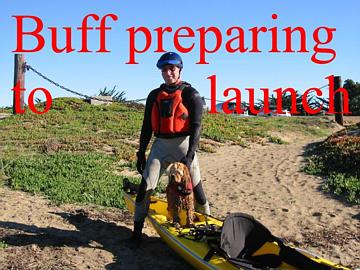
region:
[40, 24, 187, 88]
the sky is visible and clear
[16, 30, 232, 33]
the sky is visible and clear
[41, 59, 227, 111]
the sky is visible and clear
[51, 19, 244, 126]
the sky is visible and clear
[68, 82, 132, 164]
a rope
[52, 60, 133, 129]
a rope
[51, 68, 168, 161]
a rope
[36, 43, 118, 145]
a rope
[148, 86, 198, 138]
black and orange life vest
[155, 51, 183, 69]
a helmet for safety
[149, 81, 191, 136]
an orange life vest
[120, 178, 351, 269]
a yellow ocean kayak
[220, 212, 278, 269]
a black vinyl kayak seat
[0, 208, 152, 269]
a shadow of the person and kayak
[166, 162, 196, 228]
a brown dog in the kayak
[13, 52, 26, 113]
a gate post with a chain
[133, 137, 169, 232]
grey wet suit pants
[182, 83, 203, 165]
a black wet suit top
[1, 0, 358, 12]
clear blue sky without any clouds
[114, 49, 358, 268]
a guy preparing to launch his boat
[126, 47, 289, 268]
a guy with his dog preparing to launch his boat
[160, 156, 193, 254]
a dog on a yellow boat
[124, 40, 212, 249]
a guy with helmet and sunglasses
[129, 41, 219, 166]
a guy in life vest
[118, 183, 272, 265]
a yellow boat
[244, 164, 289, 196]
a sandy road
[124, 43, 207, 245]
a guy in a wet suit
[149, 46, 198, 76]
a blue helmet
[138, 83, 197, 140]
an orange vest